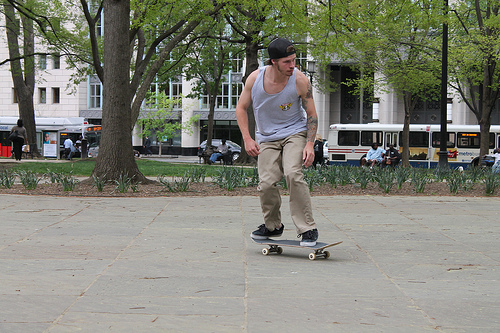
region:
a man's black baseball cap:
[264, 40, 299, 62]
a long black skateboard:
[247, 232, 342, 264]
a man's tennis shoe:
[296, 231, 321, 247]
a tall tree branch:
[87, 0, 147, 181]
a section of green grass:
[136, 149, 188, 175]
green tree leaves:
[383, 60, 435, 94]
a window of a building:
[87, 83, 101, 105]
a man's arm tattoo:
[305, 109, 317, 141]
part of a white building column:
[182, 72, 207, 148]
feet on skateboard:
[240, 221, 342, 261]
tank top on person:
[243, 74, 312, 148]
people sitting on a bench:
[339, 140, 406, 185]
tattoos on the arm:
[297, 70, 317, 139]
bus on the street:
[328, 129, 498, 174]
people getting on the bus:
[56, 131, 98, 168]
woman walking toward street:
[5, 115, 31, 189]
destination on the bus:
[81, 114, 106, 132]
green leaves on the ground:
[0, 172, 244, 202]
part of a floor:
[188, 260, 222, 298]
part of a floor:
[376, 222, 412, 274]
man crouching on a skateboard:
[237, 38, 339, 256]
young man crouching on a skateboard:
[236, 38, 340, 258]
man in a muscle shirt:
[234, 37, 321, 247]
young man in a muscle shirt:
[234, 38, 318, 244]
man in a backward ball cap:
[237, 40, 319, 245]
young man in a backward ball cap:
[235, 36, 318, 245]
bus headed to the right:
[327, 124, 499, 169]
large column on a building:
[184, 38, 197, 153]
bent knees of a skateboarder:
[253, 166, 320, 197]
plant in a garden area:
[156, 173, 196, 193]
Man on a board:
[248, 229, 348, 263]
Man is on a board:
[244, 225, 347, 265]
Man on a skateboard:
[248, 228, 343, 262]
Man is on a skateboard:
[242, 231, 347, 261]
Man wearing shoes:
[245, 219, 322, 249]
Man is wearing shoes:
[249, 221, 331, 246]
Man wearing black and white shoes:
[247, 220, 324, 249]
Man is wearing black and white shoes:
[246, 217, 324, 249]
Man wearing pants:
[255, 125, 319, 236]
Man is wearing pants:
[251, 128, 320, 234]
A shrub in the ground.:
[212, 170, 242, 196]